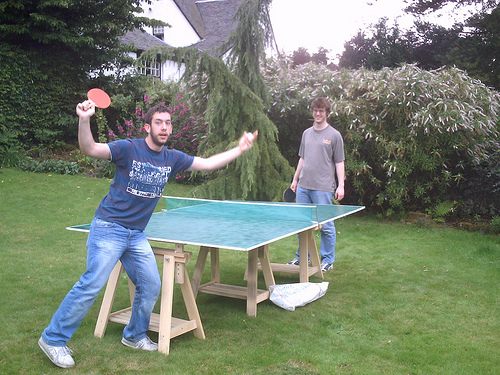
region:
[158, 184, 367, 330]
this is a table tennis court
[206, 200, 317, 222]
this is a net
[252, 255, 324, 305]
the table is wooden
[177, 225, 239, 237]
the table is green in color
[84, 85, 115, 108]
this is a racket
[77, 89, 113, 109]
the racket is small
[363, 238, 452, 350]
this is the grass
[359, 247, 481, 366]
the grass is green in color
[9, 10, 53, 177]
this is a tree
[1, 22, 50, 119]
the leaves are green in color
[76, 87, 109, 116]
A red ping pong paddle.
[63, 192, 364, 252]
A green ping pong table.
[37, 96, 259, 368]
A man in a blue shirt holding a red paddle.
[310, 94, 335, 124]
A guy standing with curly brown hair.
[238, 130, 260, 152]
A blue shirted man's left side hand.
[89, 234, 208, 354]
A wooden saw horse close to the man in blue.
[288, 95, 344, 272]
A man standing past the table with curly brown hair.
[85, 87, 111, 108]
Top red round section of a paddle.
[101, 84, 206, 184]
Purple flowers behind a man in a blue shirt.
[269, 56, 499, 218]
A long bush behind a curly haired man.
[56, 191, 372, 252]
green and white ping pong table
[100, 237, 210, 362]
brown wooden sawhorse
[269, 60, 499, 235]
bush topped with many white flowers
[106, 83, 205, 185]
green bush covered in pink flowers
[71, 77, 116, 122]
red ping pong paddle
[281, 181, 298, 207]
black ping pong paddle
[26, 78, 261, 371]
man in a blue shirt with his arms outstreched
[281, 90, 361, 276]
man in a grey shirt and blue jeans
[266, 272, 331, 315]
white bag resting on grass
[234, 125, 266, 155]
hand holding a white ping pong ball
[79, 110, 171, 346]
this is a man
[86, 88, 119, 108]
this is a racket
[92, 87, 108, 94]
the racket is red in color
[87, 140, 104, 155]
the man has a light skin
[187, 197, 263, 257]
this is a table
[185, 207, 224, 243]
the table is blue in color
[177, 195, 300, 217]
this is a net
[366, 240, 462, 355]
this is a grass area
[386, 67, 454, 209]
this is a tree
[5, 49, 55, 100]
the tree has green leaves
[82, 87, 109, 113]
Pink table tennis paddle.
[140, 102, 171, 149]
Man's face with beard.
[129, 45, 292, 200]
Evergreen tree growing slopped over.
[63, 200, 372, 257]
Green table tennis top.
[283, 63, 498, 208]
Bush growing on fence with flowers.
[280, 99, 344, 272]
Young man with black table tennis paddle.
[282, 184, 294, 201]
Black table tennis paddle.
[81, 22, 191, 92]
Neighboring house shows through greenery.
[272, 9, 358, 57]
Sun is shining brightly.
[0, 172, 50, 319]
Thick healthy green grass.